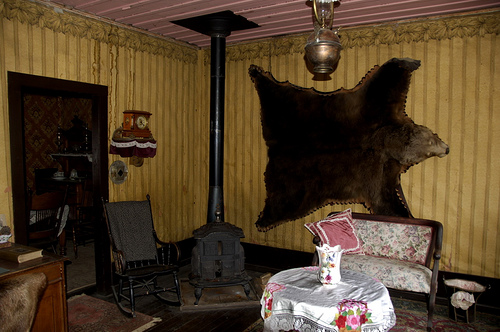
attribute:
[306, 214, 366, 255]
pillow — pink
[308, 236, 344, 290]
vase — floral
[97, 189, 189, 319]
chair — rocking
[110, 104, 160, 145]
clock — small, wooden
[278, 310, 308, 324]
tablecloth — WHITE, FLORAL, DESIGN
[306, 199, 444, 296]
chair — SOFA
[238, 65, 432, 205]
bear — BROWN, PELT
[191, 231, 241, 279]
furnace — OLD STYLE, BLACK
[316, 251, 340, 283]
vase — WHITE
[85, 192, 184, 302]
chair — ROCKING, WOODEN, BLACK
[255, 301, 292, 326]
cloth — TABLE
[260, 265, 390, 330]
table — ROUND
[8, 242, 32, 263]
book — HARD, COVERED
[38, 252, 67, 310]
space — COUNTER, WOODEN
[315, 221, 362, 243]
pillow — SINGLE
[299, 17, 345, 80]
fixture — BRONZE, METAL, LIGHT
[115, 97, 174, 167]
clock — ANTIQUE, WALL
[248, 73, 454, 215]
rug — BEARSKIN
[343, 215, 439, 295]
sofa — OLD, ANTIQUE, WOODEN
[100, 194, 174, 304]
chair — OLD, ANTIQUE, WOODEN, ROCKING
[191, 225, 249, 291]
stove — IRON, FASHIONED, OLD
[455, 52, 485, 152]
paper — STRIPED, PATTERNED, WALL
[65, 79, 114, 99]
frame — SMALL, WOODEN, DOOR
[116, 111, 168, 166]
lamp — SMALL, BROWN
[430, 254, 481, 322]
furniture — OLD, ANTIQUE, PIECE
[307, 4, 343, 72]
lamp — SMALL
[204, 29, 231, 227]
pipe — BLACK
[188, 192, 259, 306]
fireplace — black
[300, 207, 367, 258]
pillow — red, white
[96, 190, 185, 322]
rocking chair — wooden, black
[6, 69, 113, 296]
door frame — dark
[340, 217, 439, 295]
fabric — flower patterned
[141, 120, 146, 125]
clock hand — black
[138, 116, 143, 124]
clock hand — black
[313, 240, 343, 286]
vase — white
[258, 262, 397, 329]
tablecloth — white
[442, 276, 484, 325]
garbage can — antique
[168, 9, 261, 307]
furnace — black, old style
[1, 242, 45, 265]
book — hard-cover, brown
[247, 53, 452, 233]
bear pelt — brown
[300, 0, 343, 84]
light fixture — bronze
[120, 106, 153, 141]
clock — wooden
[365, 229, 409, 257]
pattern — floral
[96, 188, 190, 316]
rocking chair — black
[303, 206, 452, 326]
sofa — small, floral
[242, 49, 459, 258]
bear skin — brown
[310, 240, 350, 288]
vase — white, floral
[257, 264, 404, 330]
table cloth — white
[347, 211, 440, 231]
trim — brown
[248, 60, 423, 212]
bear — furry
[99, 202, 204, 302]
rocker — dark colored